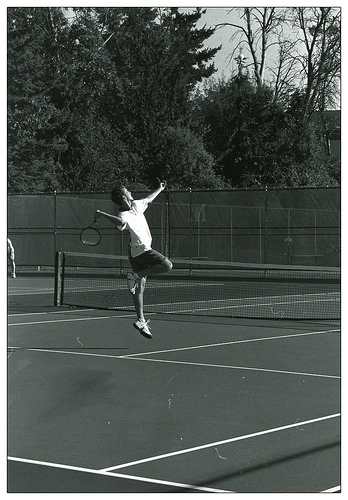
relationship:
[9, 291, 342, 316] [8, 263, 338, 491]
lines on court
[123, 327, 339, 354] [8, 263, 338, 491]
lines on court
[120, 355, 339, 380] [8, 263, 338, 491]
lines on court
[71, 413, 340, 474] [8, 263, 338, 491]
lines on court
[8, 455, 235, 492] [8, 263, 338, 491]
lines on court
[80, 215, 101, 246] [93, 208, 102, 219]
racket in hand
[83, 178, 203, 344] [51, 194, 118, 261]
man swinging racket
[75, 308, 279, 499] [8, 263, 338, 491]
lines on court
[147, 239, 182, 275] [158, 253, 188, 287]
leg bent at knee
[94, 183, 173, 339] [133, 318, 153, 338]
man wearing shoe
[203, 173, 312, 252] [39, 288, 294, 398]
tarp side of court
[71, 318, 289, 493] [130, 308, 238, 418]
lines on court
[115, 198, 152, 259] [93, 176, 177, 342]
shirt on tennis player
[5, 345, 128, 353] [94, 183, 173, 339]
shadow of man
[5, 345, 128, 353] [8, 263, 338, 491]
shadow on court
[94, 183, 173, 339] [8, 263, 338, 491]
man on court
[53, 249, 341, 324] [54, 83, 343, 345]
dividing net across court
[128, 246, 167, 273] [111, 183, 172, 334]
shorts of tennis player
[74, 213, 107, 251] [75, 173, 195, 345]
racket of player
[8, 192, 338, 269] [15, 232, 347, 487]
fenceline along court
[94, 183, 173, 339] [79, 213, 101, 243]
man swinging racquet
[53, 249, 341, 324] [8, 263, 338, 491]
dividing net on court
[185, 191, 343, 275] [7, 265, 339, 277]
fencing around perimeter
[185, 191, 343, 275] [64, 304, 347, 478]
fencing around tennis court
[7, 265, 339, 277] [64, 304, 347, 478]
perimeter of tennis court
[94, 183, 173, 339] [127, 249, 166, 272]
man wearing shorts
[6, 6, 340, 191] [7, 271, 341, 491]
trees behind tennis court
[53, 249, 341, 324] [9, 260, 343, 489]
dividing net for court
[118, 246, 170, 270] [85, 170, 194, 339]
shorts of player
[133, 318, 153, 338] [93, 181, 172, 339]
shoe of tennis player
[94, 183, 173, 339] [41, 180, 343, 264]
man in back ground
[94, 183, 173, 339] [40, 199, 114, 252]
man swinging tennis racquet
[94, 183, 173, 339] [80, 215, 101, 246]
man has a racket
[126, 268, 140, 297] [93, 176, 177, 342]
shoe of tennis player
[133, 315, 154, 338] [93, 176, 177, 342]
shoe of tennis player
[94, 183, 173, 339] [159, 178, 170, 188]
man with ball